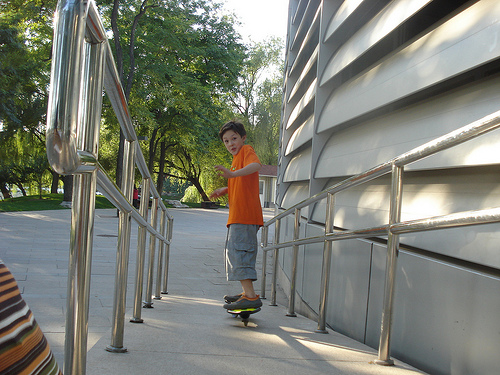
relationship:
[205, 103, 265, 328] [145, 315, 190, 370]
boy skateboarding down ramp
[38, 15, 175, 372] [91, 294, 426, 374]
railings on side of ramp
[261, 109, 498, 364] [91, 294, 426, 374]
railings on side of ramp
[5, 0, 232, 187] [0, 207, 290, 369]
trees at edge of patio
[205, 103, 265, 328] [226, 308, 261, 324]
boy standing on board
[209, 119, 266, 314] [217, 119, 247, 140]
kid with dark hair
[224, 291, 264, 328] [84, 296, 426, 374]
skateboard on a walkway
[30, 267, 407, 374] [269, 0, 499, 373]
paved area near a building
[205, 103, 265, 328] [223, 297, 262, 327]
boy on a skateboard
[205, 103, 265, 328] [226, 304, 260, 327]
boy riding a skateboard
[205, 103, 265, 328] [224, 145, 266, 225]
boy has a shirt